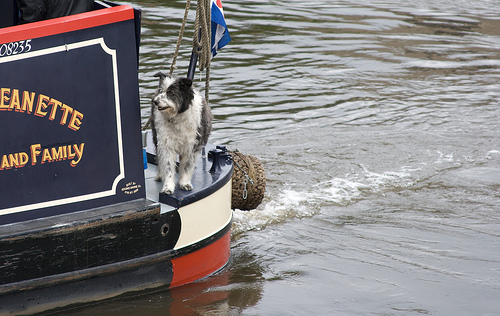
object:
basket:
[229, 148, 267, 214]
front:
[0, 5, 237, 315]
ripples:
[117, 0, 500, 293]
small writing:
[125, 180, 136, 187]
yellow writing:
[1, 86, 84, 132]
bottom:
[0, 215, 236, 315]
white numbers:
[20, 38, 32, 54]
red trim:
[0, 2, 137, 49]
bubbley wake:
[149, 69, 214, 198]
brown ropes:
[165, 0, 195, 79]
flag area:
[207, 0, 230, 61]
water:
[41, 0, 500, 316]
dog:
[150, 69, 213, 195]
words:
[0, 151, 29, 170]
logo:
[120, 181, 140, 196]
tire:
[138, 124, 152, 173]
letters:
[67, 109, 85, 133]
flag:
[207, 0, 232, 60]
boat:
[0, 0, 237, 315]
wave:
[229, 147, 499, 236]